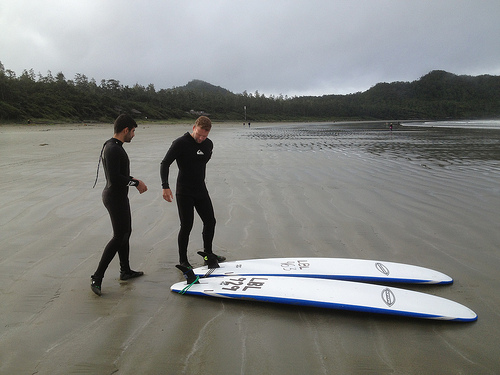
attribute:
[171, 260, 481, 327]
surfboard — part , blue, white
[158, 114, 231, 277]
man — planning, on vacation, enjoying, walking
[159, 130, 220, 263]
wetsuit — black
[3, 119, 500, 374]
beach — wet, part , ground 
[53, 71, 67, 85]
trees — pine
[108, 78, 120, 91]
trees — pine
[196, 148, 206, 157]
logo — white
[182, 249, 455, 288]
surfboard — part 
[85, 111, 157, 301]
man — planning, surfer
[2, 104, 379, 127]
bank — grassy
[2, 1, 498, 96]
sky — gray, cloudy